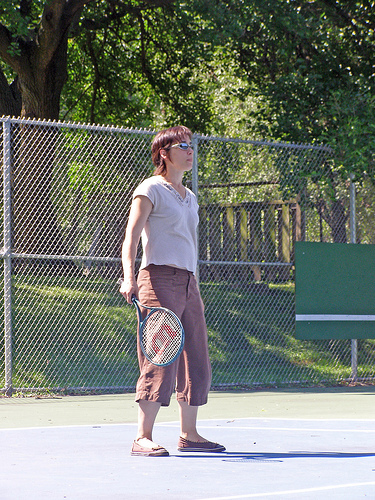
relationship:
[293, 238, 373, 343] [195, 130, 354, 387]
green board attached to fence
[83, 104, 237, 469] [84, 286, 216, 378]
girl holding racket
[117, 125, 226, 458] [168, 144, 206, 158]
girl wearing sunglasses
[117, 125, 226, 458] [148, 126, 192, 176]
girl has hair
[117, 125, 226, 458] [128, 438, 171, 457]
girl has sneaker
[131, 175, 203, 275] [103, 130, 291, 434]
shirt on woman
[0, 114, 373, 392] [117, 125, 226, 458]
fence behind girl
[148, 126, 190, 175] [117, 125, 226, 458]
hair on girl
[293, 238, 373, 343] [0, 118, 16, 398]
green board on pole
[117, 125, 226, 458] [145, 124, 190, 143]
girl has hair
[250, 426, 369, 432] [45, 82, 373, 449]
lines on tennis court.